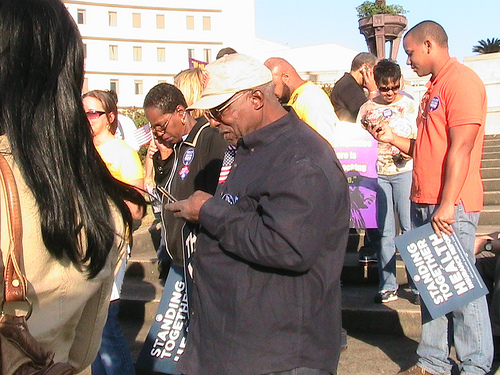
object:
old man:
[153, 54, 350, 373]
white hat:
[186, 54, 276, 110]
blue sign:
[393, 222, 490, 320]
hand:
[427, 206, 458, 239]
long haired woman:
[0, 1, 141, 373]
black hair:
[0, 1, 124, 275]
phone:
[156, 184, 184, 211]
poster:
[330, 143, 378, 231]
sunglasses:
[84, 109, 105, 120]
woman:
[78, 90, 145, 223]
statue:
[355, 14, 406, 56]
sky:
[254, 2, 336, 58]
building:
[51, 0, 256, 109]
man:
[359, 18, 496, 372]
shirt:
[412, 56, 488, 216]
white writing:
[408, 233, 476, 304]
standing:
[404, 243, 444, 308]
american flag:
[133, 122, 157, 151]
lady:
[143, 82, 223, 269]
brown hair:
[84, 91, 119, 135]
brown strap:
[0, 152, 37, 335]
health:
[426, 233, 469, 296]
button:
[430, 96, 439, 111]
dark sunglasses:
[379, 85, 399, 92]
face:
[376, 74, 401, 101]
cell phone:
[361, 119, 382, 133]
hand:
[365, 123, 396, 145]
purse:
[0, 319, 47, 373]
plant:
[354, 2, 376, 17]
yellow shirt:
[290, 81, 344, 148]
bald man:
[261, 57, 340, 143]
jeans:
[379, 167, 413, 300]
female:
[359, 62, 418, 306]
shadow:
[118, 264, 156, 352]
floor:
[127, 235, 150, 342]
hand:
[163, 189, 206, 223]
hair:
[147, 82, 185, 111]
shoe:
[375, 287, 401, 303]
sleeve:
[198, 194, 247, 248]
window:
[132, 13, 142, 28]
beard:
[278, 82, 293, 103]